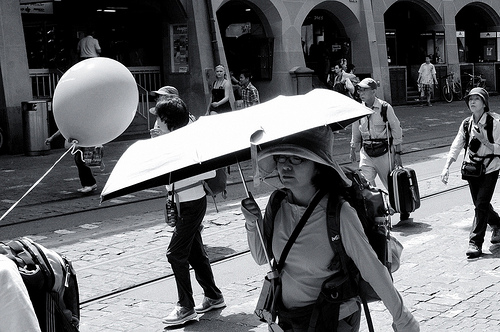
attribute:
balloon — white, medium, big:
[41, 54, 152, 151]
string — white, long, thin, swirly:
[2, 137, 79, 227]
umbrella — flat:
[111, 87, 351, 269]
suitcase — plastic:
[379, 163, 422, 220]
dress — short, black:
[205, 85, 235, 112]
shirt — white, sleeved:
[452, 113, 499, 195]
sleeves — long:
[447, 117, 468, 162]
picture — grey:
[3, 7, 494, 328]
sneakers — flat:
[155, 299, 237, 323]